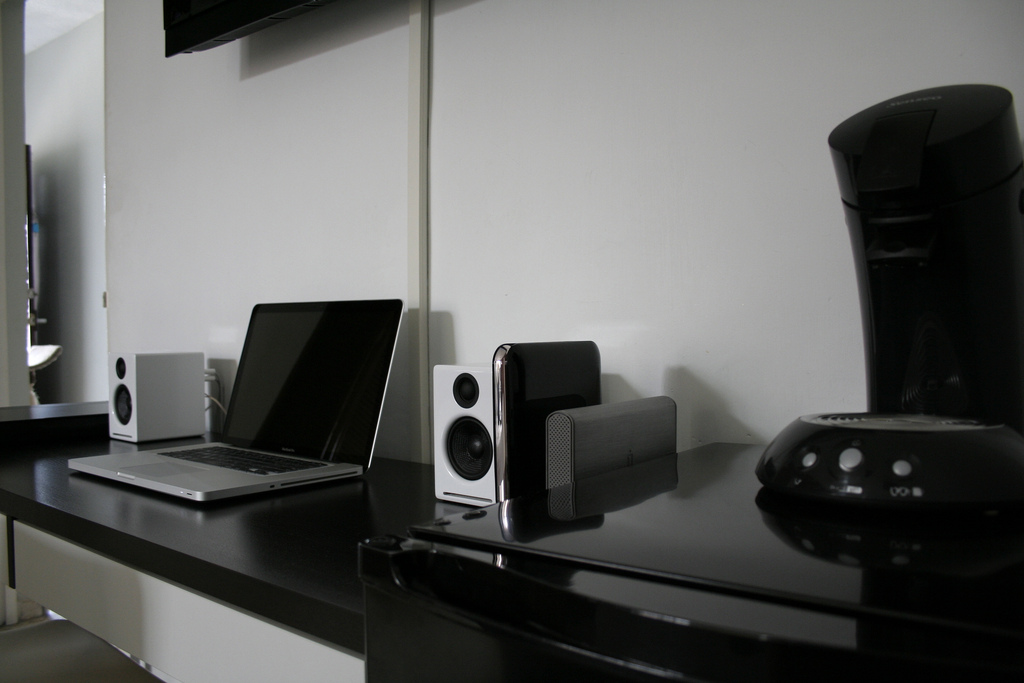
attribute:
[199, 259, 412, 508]
laptop — silver, open, black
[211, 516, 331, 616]
desk — orangized, full, neat, black, small, smooth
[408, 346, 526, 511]
speaker — round, black, white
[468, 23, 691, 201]
wall — clean, white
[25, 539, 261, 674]
drawer — closed, long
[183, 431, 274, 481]
keyboard — black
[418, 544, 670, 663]
fridge — black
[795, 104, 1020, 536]
coffee maker — new, black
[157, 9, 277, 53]
tv — hanging